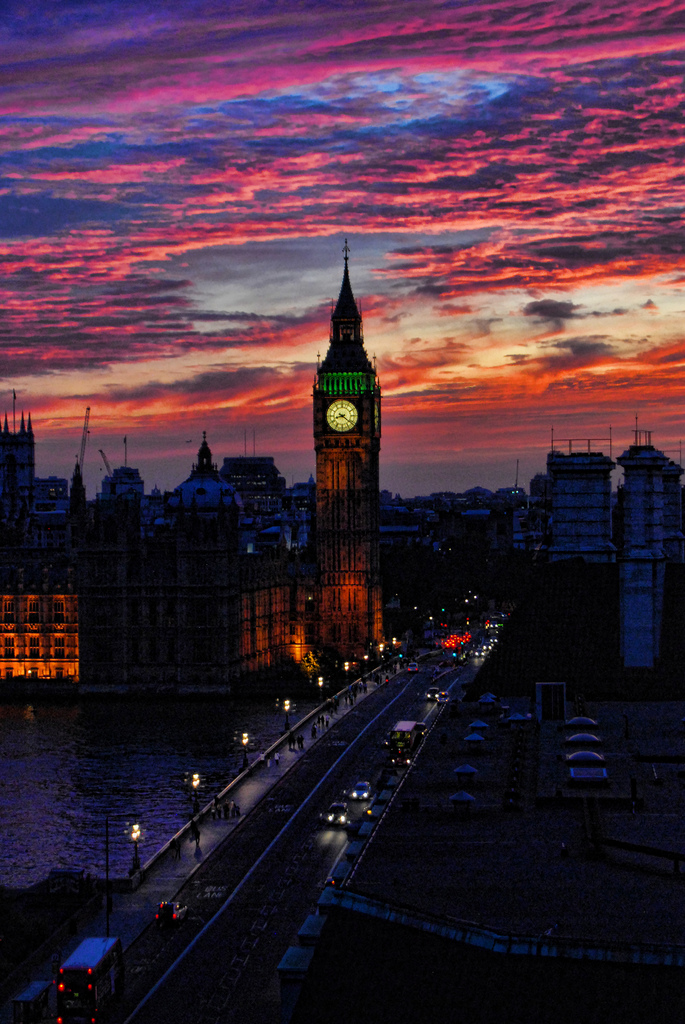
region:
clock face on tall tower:
[323, 399, 358, 433]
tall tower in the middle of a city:
[307, 233, 384, 661]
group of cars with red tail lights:
[440, 629, 471, 651]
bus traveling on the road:
[48, 934, 131, 1018]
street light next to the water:
[128, 821, 146, 872]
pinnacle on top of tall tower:
[338, 237, 359, 268]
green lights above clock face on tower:
[314, 369, 376, 396]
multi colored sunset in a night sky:
[27, 80, 666, 405]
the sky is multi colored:
[52, 77, 656, 378]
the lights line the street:
[178, 650, 346, 865]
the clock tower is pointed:
[269, 210, 413, 512]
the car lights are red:
[130, 881, 195, 945]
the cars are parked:
[517, 671, 643, 790]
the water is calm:
[12, 683, 188, 812]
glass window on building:
[49, 647, 60, 658]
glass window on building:
[24, 636, 37, 641]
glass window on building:
[6, 649, 12, 655]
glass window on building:
[51, 600, 57, 607]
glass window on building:
[28, 601, 34, 610]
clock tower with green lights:
[312, 220, 403, 661]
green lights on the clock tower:
[315, 368, 369, 392]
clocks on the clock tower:
[327, 399, 381, 439]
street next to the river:
[101, 626, 489, 1022]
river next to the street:
[2, 685, 313, 901]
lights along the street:
[125, 630, 408, 865]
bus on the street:
[59, 937, 124, 1012]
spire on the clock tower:
[322, 229, 367, 315]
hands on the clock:
[330, 408, 354, 429]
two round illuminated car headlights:
[325, 812, 346, 823]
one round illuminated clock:
[325, 398, 362, 435]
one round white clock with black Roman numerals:
[324, 400, 363, 434]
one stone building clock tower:
[304, 241, 393, 654]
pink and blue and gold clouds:
[21, 32, 672, 252]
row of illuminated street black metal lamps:
[120, 635, 412, 893]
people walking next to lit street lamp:
[187, 769, 246, 825]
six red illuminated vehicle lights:
[54, 964, 104, 1022]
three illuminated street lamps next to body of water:
[27, 725, 255, 844]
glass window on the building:
[53, 648, 65, 656]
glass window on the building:
[29, 649, 40, 656]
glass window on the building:
[26, 636, 36, 642]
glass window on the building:
[28, 599, 36, 609]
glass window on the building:
[0, 643, 8, 652]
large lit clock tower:
[275, 224, 401, 633]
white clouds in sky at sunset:
[72, 163, 123, 258]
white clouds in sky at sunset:
[65, 296, 132, 337]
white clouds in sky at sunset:
[497, 249, 565, 307]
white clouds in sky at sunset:
[254, 54, 379, 134]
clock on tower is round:
[327, 398, 358, 432]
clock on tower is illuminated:
[324, 398, 358, 437]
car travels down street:
[324, 796, 349, 830]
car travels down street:
[349, 777, 372, 802]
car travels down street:
[425, 686, 437, 701]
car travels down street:
[156, 899, 193, 920]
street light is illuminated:
[104, 811, 144, 933]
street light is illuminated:
[180, 772, 206, 841]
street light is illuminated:
[231, 729, 259, 770]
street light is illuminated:
[274, 693, 297, 732]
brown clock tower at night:
[285, 281, 378, 635]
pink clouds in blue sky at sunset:
[27, 22, 107, 119]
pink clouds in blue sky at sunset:
[56, 253, 104, 296]